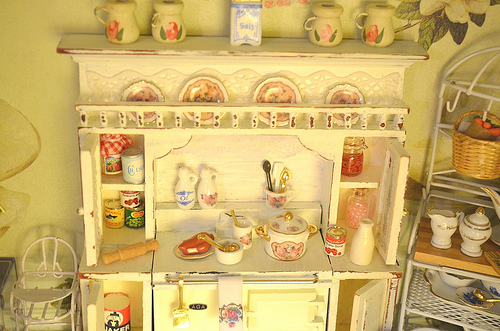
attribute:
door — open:
[347, 275, 388, 329]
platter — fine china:
[421, 267, 498, 322]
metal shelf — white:
[393, 44, 499, 329]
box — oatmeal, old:
[110, 284, 140, 323]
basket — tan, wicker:
[450, 134, 497, 181]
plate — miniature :
[112, 76, 168, 132]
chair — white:
[14, 230, 81, 330]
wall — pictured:
[0, 98, 184, 218]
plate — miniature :
[117, 78, 177, 137]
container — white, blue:
[203, 10, 290, 60]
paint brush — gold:
[169, 277, 191, 328]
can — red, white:
[326, 227, 345, 255]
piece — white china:
[256, 210, 320, 262]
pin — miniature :
[99, 236, 159, 265]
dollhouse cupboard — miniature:
[50, 28, 415, 329]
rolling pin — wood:
[98, 236, 159, 266]